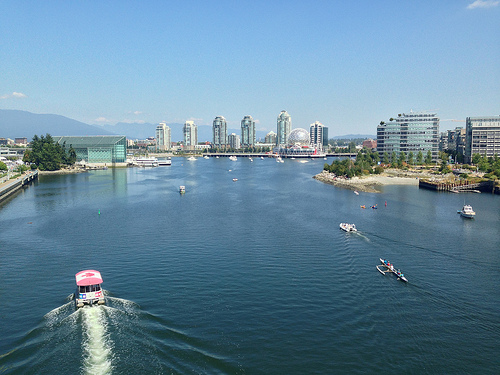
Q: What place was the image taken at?
A: It was taken at the city.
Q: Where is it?
A: This is at the city.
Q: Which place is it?
A: It is a city.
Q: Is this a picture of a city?
A: Yes, it is showing a city.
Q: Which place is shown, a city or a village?
A: It is a city.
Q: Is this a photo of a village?
A: No, the picture is showing a city.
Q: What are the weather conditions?
A: It is cloudless.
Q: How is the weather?
A: It is cloudless.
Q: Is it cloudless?
A: Yes, it is cloudless.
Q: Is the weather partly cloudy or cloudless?
A: It is cloudless.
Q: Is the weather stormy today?
A: No, it is cloudless.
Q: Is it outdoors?
A: Yes, it is outdoors.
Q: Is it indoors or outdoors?
A: It is outdoors.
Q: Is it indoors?
A: No, it is outdoors.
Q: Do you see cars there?
A: No, there are no cars.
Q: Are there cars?
A: No, there are no cars.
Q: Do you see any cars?
A: No, there are no cars.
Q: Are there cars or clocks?
A: No, there are no cars or clocks.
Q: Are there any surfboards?
A: No, there are no surfboards.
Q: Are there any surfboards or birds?
A: No, there are no surfboards or birds.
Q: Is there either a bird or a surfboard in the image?
A: No, there are no surfboards or birds.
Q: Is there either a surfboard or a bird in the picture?
A: No, there are no surfboards or birds.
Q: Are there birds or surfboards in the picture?
A: No, there are no surfboards or birds.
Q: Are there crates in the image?
A: No, there are no crates.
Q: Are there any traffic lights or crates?
A: No, there are no crates or traffic lights.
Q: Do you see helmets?
A: No, there are no helmets.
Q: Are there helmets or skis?
A: No, there are no helmets or skis.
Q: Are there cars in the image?
A: No, there are no cars.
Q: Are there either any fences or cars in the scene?
A: No, there are no cars or fences.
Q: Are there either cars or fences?
A: No, there are no cars or fences.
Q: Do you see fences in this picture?
A: No, there are no fences.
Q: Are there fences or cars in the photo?
A: No, there are no fences or cars.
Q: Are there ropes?
A: No, there are no ropes.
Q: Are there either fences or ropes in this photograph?
A: No, there are no ropes or fences.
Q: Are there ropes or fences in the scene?
A: No, there are no ropes or fences.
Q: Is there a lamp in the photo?
A: No, there are no lamps.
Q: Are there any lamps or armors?
A: No, there are no lamps or armors.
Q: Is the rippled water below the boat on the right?
A: Yes, the water is below the boat.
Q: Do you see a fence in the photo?
A: No, there are no fences.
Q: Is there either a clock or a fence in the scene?
A: No, there are no fences or clocks.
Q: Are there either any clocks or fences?
A: No, there are no fences or clocks.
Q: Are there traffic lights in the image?
A: No, there are no traffic lights.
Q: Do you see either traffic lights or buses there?
A: No, there are no traffic lights or buses.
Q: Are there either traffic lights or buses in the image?
A: No, there are no traffic lights or buses.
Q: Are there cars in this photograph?
A: No, there are no cars.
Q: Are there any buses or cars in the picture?
A: No, there are no cars or buses.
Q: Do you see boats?
A: Yes, there is a boat.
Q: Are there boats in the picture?
A: Yes, there is a boat.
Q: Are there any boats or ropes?
A: Yes, there is a boat.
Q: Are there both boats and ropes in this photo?
A: No, there is a boat but no ropes.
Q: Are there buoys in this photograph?
A: No, there are no buoys.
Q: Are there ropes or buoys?
A: No, there are no buoys or ropes.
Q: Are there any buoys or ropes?
A: No, there are no buoys or ropes.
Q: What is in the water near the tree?
A: The boat is in the water.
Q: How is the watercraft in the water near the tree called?
A: The watercraft is a boat.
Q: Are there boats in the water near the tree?
A: Yes, there is a boat in the water.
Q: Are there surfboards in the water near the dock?
A: No, there is a boat in the water.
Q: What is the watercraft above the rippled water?
A: The watercraft is a boat.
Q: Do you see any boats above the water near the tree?
A: Yes, there is a boat above the water.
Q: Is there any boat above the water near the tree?
A: Yes, there is a boat above the water.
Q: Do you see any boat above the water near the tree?
A: Yes, there is a boat above the water.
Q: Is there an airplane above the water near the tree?
A: No, there is a boat above the water.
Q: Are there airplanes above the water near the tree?
A: No, there is a boat above the water.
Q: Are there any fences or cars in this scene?
A: No, there are no cars or fences.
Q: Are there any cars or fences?
A: No, there are no cars or fences.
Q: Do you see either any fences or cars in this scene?
A: No, there are no cars or fences.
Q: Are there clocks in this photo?
A: No, there are no clocks.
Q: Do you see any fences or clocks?
A: No, there are no clocks or fences.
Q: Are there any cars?
A: No, there are no cars.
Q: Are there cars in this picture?
A: No, there are no cars.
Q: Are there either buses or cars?
A: No, there are no cars or buses.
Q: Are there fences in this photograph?
A: No, there are no fences.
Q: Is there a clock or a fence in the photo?
A: No, there are no fences or clocks.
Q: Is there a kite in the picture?
A: No, there are no kites.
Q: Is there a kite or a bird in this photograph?
A: No, there are no kites or birds.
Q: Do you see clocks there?
A: No, there are no clocks.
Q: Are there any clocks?
A: No, there are no clocks.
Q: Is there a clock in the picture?
A: No, there are no clocks.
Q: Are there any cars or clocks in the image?
A: No, there are no clocks or cars.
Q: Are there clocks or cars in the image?
A: No, there are no clocks or cars.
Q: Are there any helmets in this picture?
A: No, there are no helmets.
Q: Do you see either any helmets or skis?
A: No, there are no helmets or skis.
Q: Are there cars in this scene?
A: No, there are no cars.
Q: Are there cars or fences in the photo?
A: No, there are no cars or fences.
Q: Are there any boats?
A: Yes, there is a boat.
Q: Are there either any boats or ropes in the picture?
A: Yes, there is a boat.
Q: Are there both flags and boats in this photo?
A: No, there is a boat but no flags.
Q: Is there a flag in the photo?
A: No, there are no flags.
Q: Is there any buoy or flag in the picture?
A: No, there are no flags or buoys.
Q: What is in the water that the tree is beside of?
A: The boat is in the water.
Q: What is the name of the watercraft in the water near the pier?
A: The watercraft is a boat.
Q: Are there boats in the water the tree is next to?
A: Yes, there is a boat in the water.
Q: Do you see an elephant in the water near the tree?
A: No, there is a boat in the water.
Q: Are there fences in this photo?
A: No, there are no fences.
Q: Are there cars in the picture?
A: No, there are no cars.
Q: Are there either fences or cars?
A: No, there are no cars or fences.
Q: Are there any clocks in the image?
A: No, there are no clocks.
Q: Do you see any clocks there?
A: No, there are no clocks.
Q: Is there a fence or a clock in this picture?
A: No, there are no clocks or fences.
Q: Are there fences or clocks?
A: No, there are no clocks or fences.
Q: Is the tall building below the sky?
A: Yes, the building is below the sky.